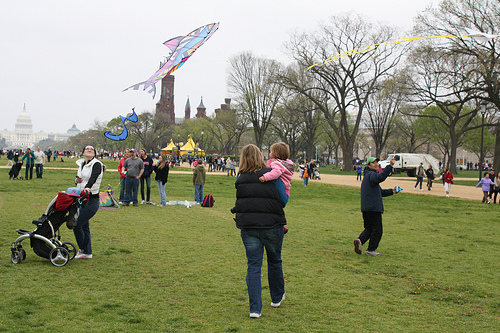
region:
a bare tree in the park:
[407, 1, 498, 174]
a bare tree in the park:
[390, 48, 490, 177]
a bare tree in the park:
[262, 9, 412, 171]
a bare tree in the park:
[227, 52, 282, 146]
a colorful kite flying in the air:
[105, 23, 222, 141]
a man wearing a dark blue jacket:
[353, 156, 403, 258]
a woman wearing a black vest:
[230, 144, 296, 318]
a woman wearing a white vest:
[12, 144, 102, 267]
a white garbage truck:
[376, 154, 443, 175]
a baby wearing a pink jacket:
[260, 141, 298, 235]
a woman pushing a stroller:
[5, 132, 123, 274]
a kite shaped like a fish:
[97, 13, 224, 141]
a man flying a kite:
[348, 148, 415, 278]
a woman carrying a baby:
[225, 130, 309, 315]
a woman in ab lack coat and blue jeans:
[222, 138, 285, 317]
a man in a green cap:
[352, 150, 397, 275]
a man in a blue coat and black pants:
[354, 135, 395, 262]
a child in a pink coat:
[259, 143, 296, 210]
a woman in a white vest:
[68, 136, 109, 266]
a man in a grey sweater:
[118, 141, 148, 213]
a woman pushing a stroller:
[13, 131, 149, 330]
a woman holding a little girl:
[213, 134, 322, 299]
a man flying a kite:
[131, 30, 453, 280]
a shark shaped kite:
[101, 15, 241, 142]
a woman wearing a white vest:
[61, 130, 108, 200]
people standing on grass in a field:
[42, 110, 289, 294]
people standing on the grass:
[3, 126, 212, 171]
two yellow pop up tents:
[138, 124, 215, 156]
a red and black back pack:
[191, 178, 224, 215]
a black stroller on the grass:
[5, 174, 113, 299]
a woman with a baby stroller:
[10, 142, 102, 269]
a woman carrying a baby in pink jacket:
[229, 142, 299, 319]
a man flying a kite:
[353, 158, 401, 255]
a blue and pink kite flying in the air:
[103, 22, 223, 140]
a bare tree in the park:
[264, 16, 412, 173]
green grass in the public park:
[0, 152, 495, 327]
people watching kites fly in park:
[116, 146, 167, 203]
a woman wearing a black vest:
[230, 143, 286, 318]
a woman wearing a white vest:
[75, 145, 103, 260]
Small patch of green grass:
[348, 285, 371, 305]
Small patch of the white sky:
[71, 63, 93, 87]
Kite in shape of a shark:
[123, 18, 225, 97]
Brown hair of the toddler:
[271, 142, 288, 156]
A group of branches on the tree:
[339, 18, 360, 37]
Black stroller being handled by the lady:
[11, 189, 80, 269]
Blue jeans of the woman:
[244, 232, 281, 302]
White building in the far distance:
[15, 110, 37, 143]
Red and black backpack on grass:
[201, 190, 216, 210]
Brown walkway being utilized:
[461, 190, 474, 201]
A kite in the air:
[123, 22, 220, 98]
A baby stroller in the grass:
[10, 183, 91, 268]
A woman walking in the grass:
[233, 142, 287, 318]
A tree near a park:
[226, 49, 287, 144]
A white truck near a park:
[376, 153, 439, 178]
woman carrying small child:
[225, 139, 299, 316]